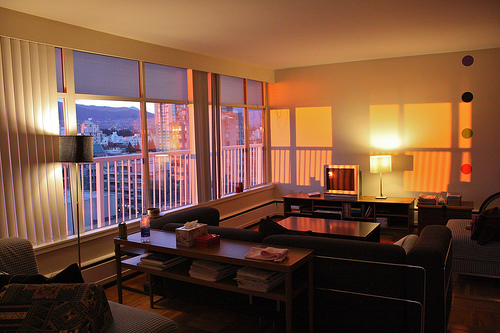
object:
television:
[321, 163, 364, 202]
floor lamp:
[55, 133, 97, 281]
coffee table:
[272, 214, 382, 243]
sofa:
[0, 233, 188, 333]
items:
[0, 282, 113, 333]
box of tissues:
[174, 217, 210, 248]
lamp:
[368, 154, 392, 200]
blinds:
[1, 35, 69, 245]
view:
[51, 42, 276, 237]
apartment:
[1, 3, 500, 332]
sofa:
[147, 204, 455, 332]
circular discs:
[460, 162, 475, 176]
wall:
[267, 49, 500, 214]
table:
[110, 226, 316, 332]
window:
[55, 48, 196, 238]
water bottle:
[139, 212, 151, 243]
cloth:
[243, 246, 291, 263]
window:
[205, 71, 273, 200]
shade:
[58, 135, 94, 163]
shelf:
[115, 248, 312, 332]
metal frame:
[308, 255, 428, 332]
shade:
[369, 153, 392, 174]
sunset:
[269, 101, 474, 203]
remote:
[307, 191, 322, 198]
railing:
[58, 143, 268, 239]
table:
[280, 193, 416, 234]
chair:
[441, 189, 500, 280]